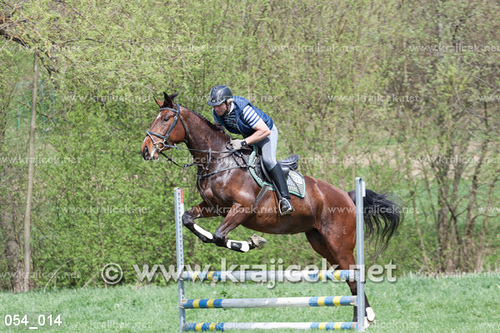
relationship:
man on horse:
[207, 84, 295, 215] [141, 90, 403, 327]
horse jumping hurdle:
[141, 90, 403, 327] [174, 267, 365, 329]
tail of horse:
[350, 186, 405, 260] [141, 90, 403, 327]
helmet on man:
[205, 83, 234, 106] [207, 84, 295, 215]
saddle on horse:
[277, 152, 301, 174] [141, 90, 403, 327]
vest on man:
[215, 96, 273, 137] [207, 84, 295, 215]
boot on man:
[269, 160, 295, 215] [207, 84, 295, 215]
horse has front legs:
[141, 90, 403, 327] [180, 197, 268, 252]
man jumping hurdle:
[207, 84, 295, 215] [174, 267, 365, 329]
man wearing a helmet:
[207, 84, 295, 215] [205, 83, 234, 106]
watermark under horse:
[99, 257, 397, 288] [141, 90, 403, 327]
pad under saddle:
[251, 151, 310, 199] [277, 152, 301, 174]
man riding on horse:
[207, 84, 295, 215] [141, 90, 403, 327]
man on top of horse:
[207, 84, 295, 215] [141, 90, 403, 327]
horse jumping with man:
[141, 90, 403, 327] [207, 84, 295, 215]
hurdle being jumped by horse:
[174, 267, 365, 329] [141, 90, 403, 327]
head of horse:
[141, 91, 188, 162] [141, 90, 403, 327]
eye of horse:
[163, 116, 170, 121] [141, 90, 403, 327]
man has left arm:
[207, 84, 295, 215] [229, 105, 274, 153]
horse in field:
[141, 90, 403, 327] [0, 271, 499, 333]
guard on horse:
[183, 215, 213, 244] [141, 90, 403, 327]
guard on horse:
[223, 238, 250, 256] [141, 90, 403, 327]